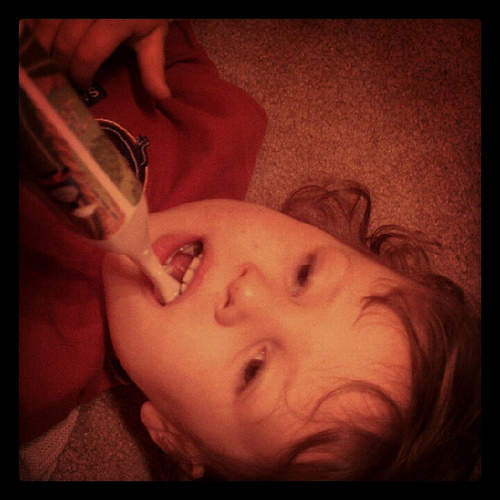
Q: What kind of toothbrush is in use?
A: An electric one.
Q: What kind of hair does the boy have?
A: Brown.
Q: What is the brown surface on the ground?
A: The carpet.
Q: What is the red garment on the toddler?
A: A shirt.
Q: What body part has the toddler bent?
A: The hand.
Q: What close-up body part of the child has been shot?
A: The face.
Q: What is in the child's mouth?
A: A toothbrush.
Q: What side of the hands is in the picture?
A: The right.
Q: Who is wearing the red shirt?
A: The child.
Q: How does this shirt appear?
A: Red.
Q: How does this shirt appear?
A: Red.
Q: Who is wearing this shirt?
A: Child.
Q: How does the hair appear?
A: Curly.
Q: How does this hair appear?
A: Curly.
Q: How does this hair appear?
A: Curly.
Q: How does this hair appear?
A: Curly.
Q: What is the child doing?
A: Brushing teeth.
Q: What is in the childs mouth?
A: Tootbrush.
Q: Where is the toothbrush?
A: In childs mouth.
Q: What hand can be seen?
A: Right.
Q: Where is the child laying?
A: On the floor.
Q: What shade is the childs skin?
A: Light.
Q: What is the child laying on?
A: The carpet.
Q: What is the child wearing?
A: Red Sweatshirt.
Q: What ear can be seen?
A: Left.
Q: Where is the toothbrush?
A: In the child's mouth.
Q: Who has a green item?
A: The child.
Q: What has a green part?
A: The toothbrush.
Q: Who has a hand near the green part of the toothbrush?
A: The child.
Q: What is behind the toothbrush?
A: A red shirt.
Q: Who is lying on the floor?
A: The child.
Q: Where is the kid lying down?
A: The floor.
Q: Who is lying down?
A: The child.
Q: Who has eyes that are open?
A: The child.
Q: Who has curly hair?
A: The kid.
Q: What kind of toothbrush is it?
A: Spin brush.